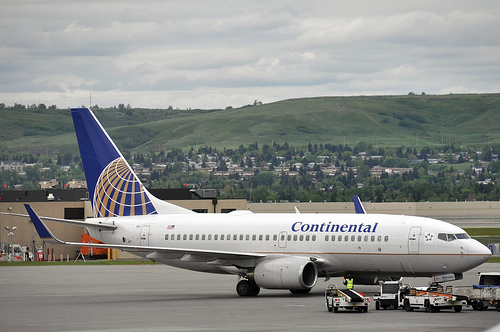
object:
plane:
[0, 106, 494, 298]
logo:
[290, 221, 379, 233]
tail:
[0, 107, 187, 253]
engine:
[253, 257, 319, 289]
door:
[408, 227, 423, 255]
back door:
[139, 225, 150, 249]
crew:
[342, 274, 354, 290]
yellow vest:
[346, 278, 355, 289]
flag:
[167, 225, 176, 231]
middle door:
[278, 230, 287, 247]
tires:
[236, 280, 260, 297]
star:
[424, 233, 434, 242]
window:
[165, 234, 170, 241]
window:
[170, 234, 175, 241]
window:
[177, 234, 182, 240]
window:
[182, 234, 187, 241]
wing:
[22, 201, 325, 265]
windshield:
[438, 233, 471, 243]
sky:
[0, 1, 499, 113]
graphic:
[92, 156, 159, 217]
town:
[1, 150, 499, 201]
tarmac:
[0, 258, 500, 331]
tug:
[80, 231, 110, 259]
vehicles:
[325, 289, 371, 312]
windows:
[384, 235, 390, 242]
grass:
[0, 259, 166, 266]